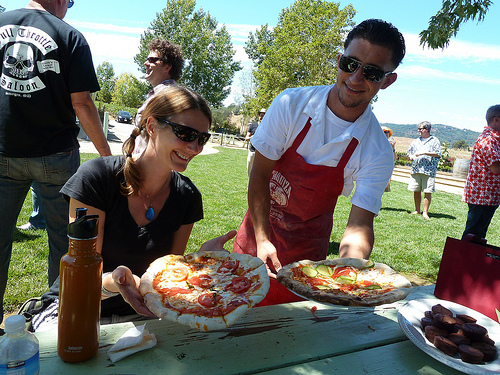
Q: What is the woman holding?
A: A pizza.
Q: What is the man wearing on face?
A: Sunglasses.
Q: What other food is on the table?
A: Brownies.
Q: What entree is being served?
A: Pizza.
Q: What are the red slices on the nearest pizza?
A: Tomatoes.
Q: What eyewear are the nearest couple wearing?
A: Sunglasses.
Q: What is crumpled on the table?
A: A white napkin.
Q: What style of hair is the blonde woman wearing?
A: A ponytail.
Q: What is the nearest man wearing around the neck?
A: Red apron.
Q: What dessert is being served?
A: Brownies.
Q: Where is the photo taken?
A: A park.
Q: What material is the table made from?
A: Wood.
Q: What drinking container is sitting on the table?
A: A thermos.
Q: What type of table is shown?
A: Picnic.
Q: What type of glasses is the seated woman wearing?
A: Sunglasses.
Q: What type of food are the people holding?
A: Pizza.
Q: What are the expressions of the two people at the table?
A: Smiles.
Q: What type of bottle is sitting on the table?
A: Water bottle.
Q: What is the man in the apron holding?
A: A pizza.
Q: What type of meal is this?
A: Picnic.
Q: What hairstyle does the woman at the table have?
A: Ponytail.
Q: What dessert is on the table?
A: Brownies.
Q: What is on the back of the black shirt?
A: Skull.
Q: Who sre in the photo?
A: People.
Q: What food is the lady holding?
A: Pizza.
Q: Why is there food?
A: To be eaten.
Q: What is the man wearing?
A: Apron.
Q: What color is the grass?
A: Green.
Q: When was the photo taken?
A: Daytime.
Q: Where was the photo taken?
A: At a picnic.